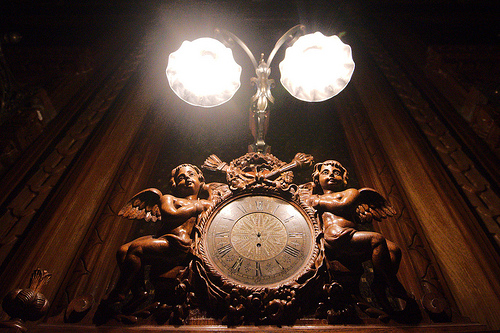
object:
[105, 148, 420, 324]
cherubs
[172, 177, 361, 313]
clock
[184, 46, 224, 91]
bulb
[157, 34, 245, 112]
shade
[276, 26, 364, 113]
edge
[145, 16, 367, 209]
fixture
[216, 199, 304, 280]
numerals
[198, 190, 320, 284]
face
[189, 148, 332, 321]
wood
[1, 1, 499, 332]
wall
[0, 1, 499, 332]
panel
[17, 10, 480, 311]
wood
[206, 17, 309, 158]
metal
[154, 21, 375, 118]
lights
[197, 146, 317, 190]
scepter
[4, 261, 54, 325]
statue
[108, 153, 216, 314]
statue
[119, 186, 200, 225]
wings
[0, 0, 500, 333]
picture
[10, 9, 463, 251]
taken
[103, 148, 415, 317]
statues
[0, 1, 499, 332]
scene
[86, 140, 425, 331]
decorations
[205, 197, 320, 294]
numbers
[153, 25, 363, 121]
lamps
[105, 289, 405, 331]
base